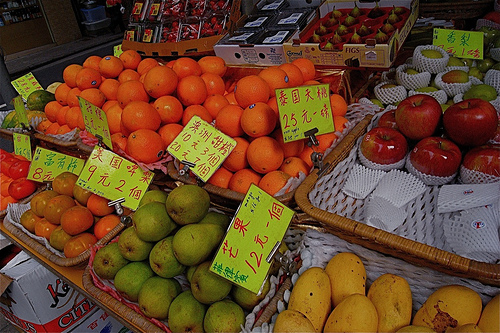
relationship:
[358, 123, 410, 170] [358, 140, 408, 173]
apple in casing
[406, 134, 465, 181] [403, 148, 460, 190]
apple in casing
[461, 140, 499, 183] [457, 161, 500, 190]
apple in casing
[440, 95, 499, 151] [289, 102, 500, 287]
apple in basket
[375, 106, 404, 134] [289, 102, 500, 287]
apple in basket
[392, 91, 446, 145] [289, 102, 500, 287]
apple in basket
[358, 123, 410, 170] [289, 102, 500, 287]
apple in basket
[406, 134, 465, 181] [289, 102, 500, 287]
apple in basket